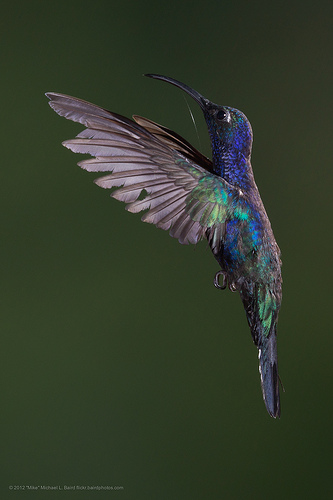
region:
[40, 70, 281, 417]
the bird is iridescent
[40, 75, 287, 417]
the bird is green, blue and black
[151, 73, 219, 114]
the bird has a long beak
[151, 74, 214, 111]
the bird has a black beak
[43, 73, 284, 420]
the bird is flying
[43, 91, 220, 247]
the wings are expanded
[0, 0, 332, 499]
the background is dark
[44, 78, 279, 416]
the bird is flying upward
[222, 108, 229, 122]
the eye has a white lining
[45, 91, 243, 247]
the animal has wings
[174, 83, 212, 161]
spider web strand on bird's beak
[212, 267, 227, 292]
right foot of hummingbird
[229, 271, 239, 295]
left foot of hummingbird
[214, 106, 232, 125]
black eye of hummingbird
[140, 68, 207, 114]
long, black beak of hummingbird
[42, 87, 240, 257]
left extended wing of hummingbird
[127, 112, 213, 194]
right extended wing of hummingbird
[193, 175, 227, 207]
teal green and light green feathers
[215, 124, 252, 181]
royal blue and purple feathers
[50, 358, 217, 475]
faded green background behind bird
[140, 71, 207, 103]
the birds beak is very long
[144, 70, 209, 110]
the birds beak is black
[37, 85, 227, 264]
the birds wing is spread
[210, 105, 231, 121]
the birds eye is black with silver around the top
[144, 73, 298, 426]
the bird is black, blue, and green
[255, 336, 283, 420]
the tip of the birds tail is black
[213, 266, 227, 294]
the talons on the feet are touching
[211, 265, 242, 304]
the birds feet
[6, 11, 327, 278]
the back ground of the picture is green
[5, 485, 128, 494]
white printing at the bottom of the picture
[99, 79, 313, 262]
the bird is flying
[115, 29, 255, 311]
the bird is flying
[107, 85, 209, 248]
the bird is flying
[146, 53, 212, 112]
beak of the humming bird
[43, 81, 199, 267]
wing feathers of the hummingbird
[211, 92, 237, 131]
black and white colored eye on the bird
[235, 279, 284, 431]
tail feathers on back of bird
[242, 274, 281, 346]
teal black and purple colors on feathers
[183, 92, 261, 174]
blue head with different shades of blue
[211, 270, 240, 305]
feet of the bird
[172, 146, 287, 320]
body of the bird with different colors: blue, teal and purple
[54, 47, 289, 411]
bird in mid air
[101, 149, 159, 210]
gap in wings not seen on other feathers